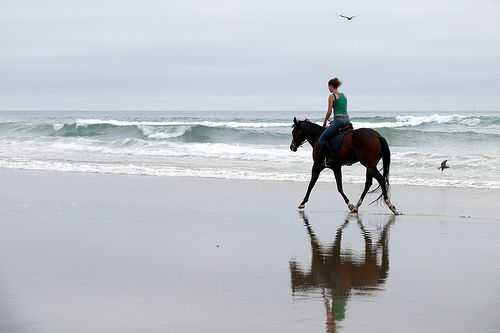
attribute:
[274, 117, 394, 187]
horse — brown, walking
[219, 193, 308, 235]
sand — wet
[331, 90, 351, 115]
top — green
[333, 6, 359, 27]
bird — flying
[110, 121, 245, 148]
waves — green